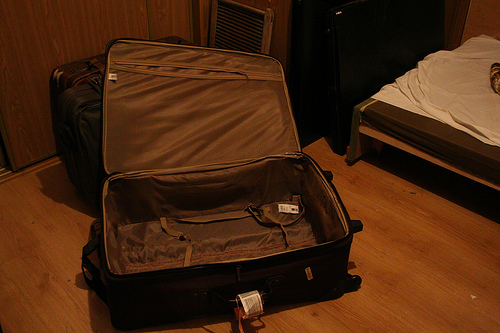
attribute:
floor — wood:
[0, 132, 497, 331]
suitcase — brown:
[80, 37, 362, 328]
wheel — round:
[349, 273, 361, 288]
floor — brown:
[371, 216, 458, 328]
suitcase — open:
[97, 42, 354, 312]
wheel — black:
[346, 267, 366, 294]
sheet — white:
[370, 25, 499, 154]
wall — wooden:
[2, 1, 210, 176]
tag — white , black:
[240, 291, 264, 320]